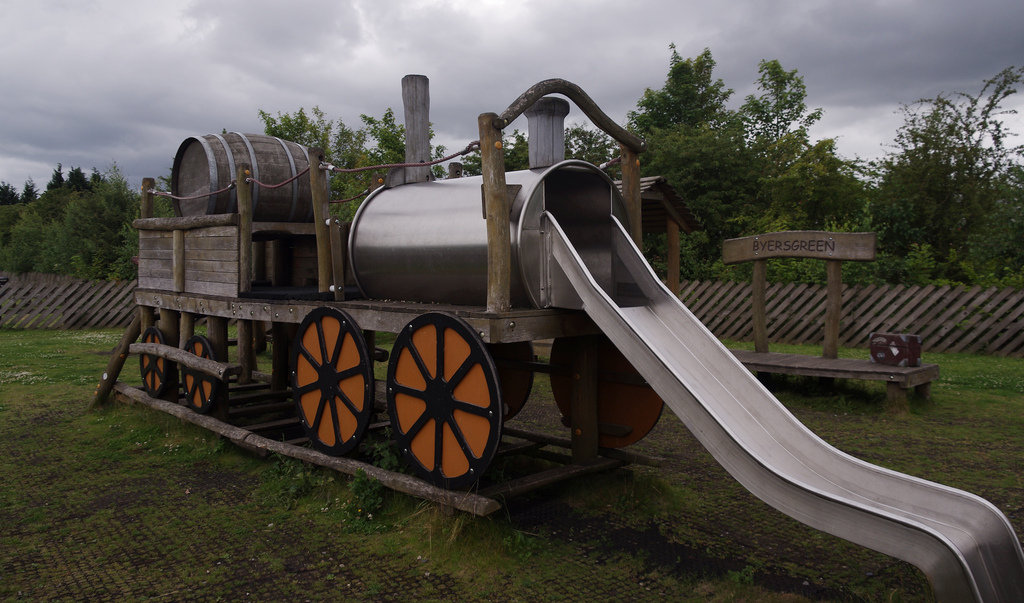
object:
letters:
[748, 239, 835, 252]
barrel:
[170, 131, 331, 223]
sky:
[0, 0, 1022, 187]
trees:
[625, 42, 1024, 278]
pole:
[476, 112, 509, 313]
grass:
[0, 441, 383, 603]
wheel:
[381, 312, 505, 491]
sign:
[722, 230, 876, 263]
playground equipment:
[98, 74, 1023, 603]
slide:
[539, 206, 1023, 603]